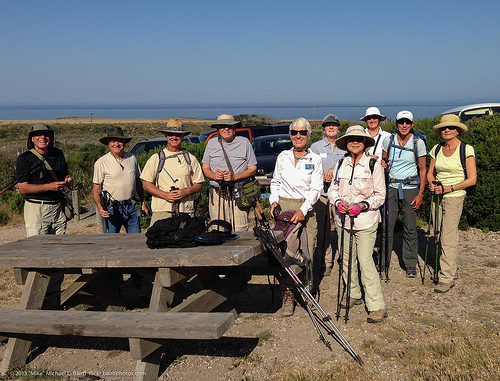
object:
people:
[423, 110, 479, 295]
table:
[1, 233, 282, 380]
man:
[14, 121, 76, 239]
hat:
[27, 122, 56, 133]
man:
[138, 118, 203, 233]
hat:
[157, 117, 191, 136]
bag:
[234, 176, 264, 210]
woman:
[325, 124, 388, 321]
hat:
[332, 124, 375, 141]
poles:
[333, 206, 354, 324]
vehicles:
[244, 133, 290, 176]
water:
[0, 102, 456, 124]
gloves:
[349, 201, 366, 216]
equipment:
[250, 224, 363, 369]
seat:
[1, 306, 237, 344]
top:
[0, 224, 285, 260]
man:
[201, 113, 261, 230]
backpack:
[458, 141, 476, 196]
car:
[132, 135, 198, 155]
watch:
[450, 184, 455, 192]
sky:
[2, 0, 500, 102]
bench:
[2, 307, 235, 380]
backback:
[159, 147, 193, 174]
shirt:
[428, 142, 476, 198]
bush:
[464, 115, 497, 230]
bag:
[145, 212, 240, 249]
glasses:
[165, 131, 186, 138]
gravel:
[276, 342, 303, 360]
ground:
[2, 220, 498, 379]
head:
[331, 126, 375, 158]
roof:
[138, 134, 199, 143]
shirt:
[268, 145, 324, 214]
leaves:
[482, 133, 498, 148]